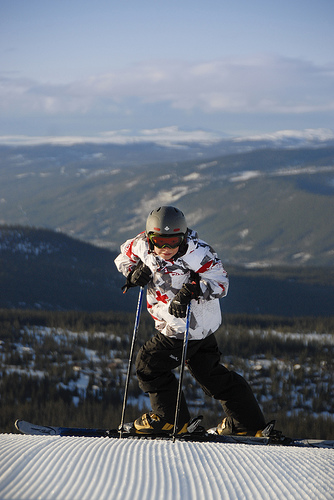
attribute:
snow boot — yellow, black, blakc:
[122, 413, 192, 438]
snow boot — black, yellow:
[203, 418, 273, 439]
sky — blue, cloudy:
[2, 3, 330, 132]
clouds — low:
[6, 52, 319, 126]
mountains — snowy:
[12, 144, 333, 250]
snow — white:
[3, 434, 332, 500]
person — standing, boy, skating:
[116, 199, 266, 423]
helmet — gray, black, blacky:
[142, 205, 191, 232]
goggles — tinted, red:
[145, 233, 186, 247]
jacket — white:
[108, 232, 234, 339]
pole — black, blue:
[114, 289, 143, 433]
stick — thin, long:
[150, 302, 196, 445]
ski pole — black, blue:
[152, 301, 194, 451]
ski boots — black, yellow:
[129, 409, 264, 440]